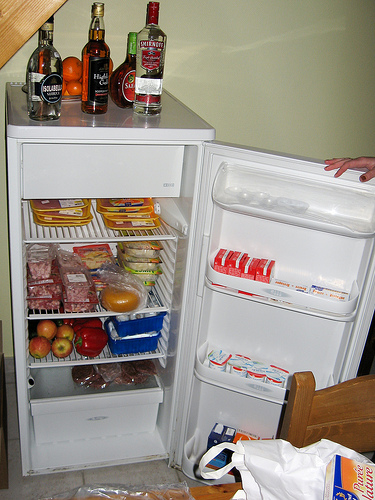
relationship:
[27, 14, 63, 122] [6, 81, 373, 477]
bottle on fridge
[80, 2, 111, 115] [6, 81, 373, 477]
bottle on fridge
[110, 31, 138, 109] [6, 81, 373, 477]
bottle on fridge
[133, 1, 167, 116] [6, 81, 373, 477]
bottle on fridge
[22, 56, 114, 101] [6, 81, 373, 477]
oranges on fridge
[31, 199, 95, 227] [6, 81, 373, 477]
meat in fridge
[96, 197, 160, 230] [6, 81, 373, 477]
meat in fridge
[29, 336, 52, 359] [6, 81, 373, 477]
apple in fridge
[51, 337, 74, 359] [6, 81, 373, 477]
apple in fridge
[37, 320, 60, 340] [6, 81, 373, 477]
apple in fridge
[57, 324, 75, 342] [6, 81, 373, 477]
apple in fridge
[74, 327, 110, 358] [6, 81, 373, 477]
red pepper in fridge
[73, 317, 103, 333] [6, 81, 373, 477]
red pepper in fridge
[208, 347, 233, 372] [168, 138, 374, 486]
yogurt in door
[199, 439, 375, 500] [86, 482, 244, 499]
bag on table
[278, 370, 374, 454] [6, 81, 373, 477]
chair in front of fridge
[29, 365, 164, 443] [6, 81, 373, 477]
drawer in fridge